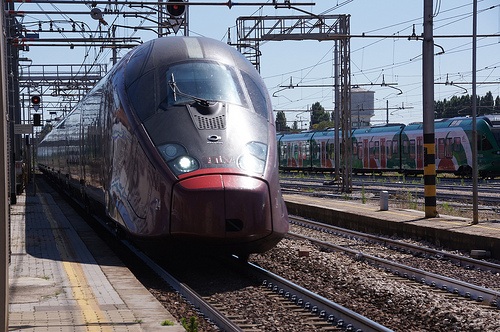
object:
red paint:
[170, 173, 273, 242]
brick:
[7, 173, 187, 332]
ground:
[388, 142, 421, 167]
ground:
[291, 129, 324, 171]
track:
[53, 183, 392, 332]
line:
[35, 189, 112, 331]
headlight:
[238, 155, 264, 173]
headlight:
[165, 144, 177, 157]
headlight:
[250, 144, 264, 155]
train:
[275, 113, 499, 180]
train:
[32, 35, 290, 263]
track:
[281, 177, 500, 205]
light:
[30, 97, 42, 105]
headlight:
[173, 155, 199, 173]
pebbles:
[188, 211, 498, 332]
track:
[283, 214, 499, 307]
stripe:
[424, 134, 434, 144]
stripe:
[424, 154, 435, 164]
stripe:
[424, 175, 435, 185]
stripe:
[425, 197, 436, 207]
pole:
[421, 0, 435, 218]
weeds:
[189, 315, 208, 331]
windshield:
[127, 61, 268, 124]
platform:
[9, 181, 185, 332]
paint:
[73, 283, 93, 310]